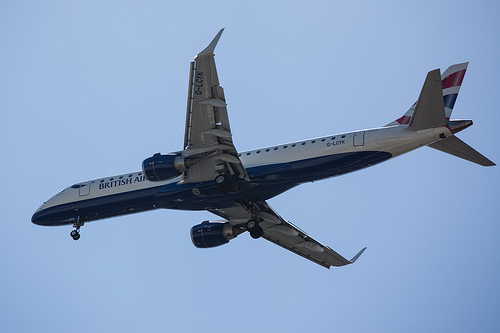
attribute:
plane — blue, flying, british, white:
[28, 22, 496, 269]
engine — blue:
[140, 153, 187, 182]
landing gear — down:
[212, 172, 239, 194]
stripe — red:
[438, 68, 467, 90]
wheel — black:
[213, 174, 227, 190]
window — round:
[291, 143, 295, 148]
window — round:
[329, 136, 336, 141]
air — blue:
[0, 1, 497, 333]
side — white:
[31, 121, 416, 214]